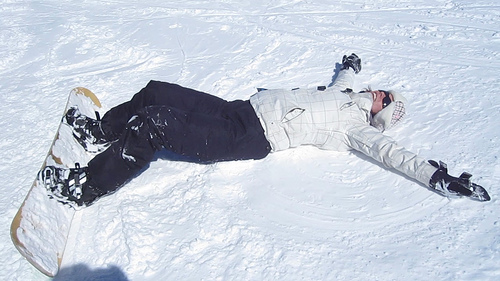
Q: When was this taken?
A: Daytime.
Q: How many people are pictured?
A: One.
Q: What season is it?
A: Winter.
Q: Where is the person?
A: On the ground.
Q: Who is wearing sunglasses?
A: The woman.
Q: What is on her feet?
A: A snowboard.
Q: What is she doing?
A: Making a snow angel.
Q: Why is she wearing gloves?
A: It is cold out.